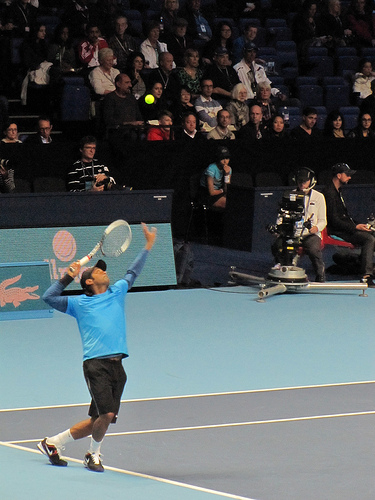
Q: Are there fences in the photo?
A: No, there are no fences.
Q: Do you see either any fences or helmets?
A: No, there are no fences or helmets.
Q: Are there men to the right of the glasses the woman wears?
A: Yes, there is a man to the right of the glasses.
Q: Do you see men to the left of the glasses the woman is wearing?
A: No, the man is to the right of the glasses.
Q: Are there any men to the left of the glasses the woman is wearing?
A: No, the man is to the right of the glasses.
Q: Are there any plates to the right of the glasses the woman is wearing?
A: No, there is a man to the right of the glasses.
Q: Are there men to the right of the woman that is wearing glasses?
A: Yes, there is a man to the right of the woman.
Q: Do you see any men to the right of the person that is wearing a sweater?
A: Yes, there is a man to the right of the woman.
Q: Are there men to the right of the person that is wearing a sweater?
A: Yes, there is a man to the right of the woman.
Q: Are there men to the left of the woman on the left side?
A: No, the man is to the right of the woman.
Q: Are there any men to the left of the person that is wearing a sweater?
A: No, the man is to the right of the woman.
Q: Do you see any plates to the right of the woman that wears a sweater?
A: No, there is a man to the right of the woman.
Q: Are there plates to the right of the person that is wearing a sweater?
A: No, there is a man to the right of the woman.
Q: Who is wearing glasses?
A: The man is wearing glasses.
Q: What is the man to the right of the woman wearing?
A: The man is wearing glasses.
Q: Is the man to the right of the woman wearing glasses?
A: Yes, the man is wearing glasses.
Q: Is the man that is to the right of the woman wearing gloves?
A: No, the man is wearing glasses.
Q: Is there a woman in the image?
A: Yes, there is a woman.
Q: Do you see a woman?
A: Yes, there is a woman.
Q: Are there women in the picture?
A: Yes, there is a woman.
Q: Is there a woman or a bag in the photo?
A: Yes, there is a woman.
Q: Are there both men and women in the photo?
A: Yes, there are both a woman and men.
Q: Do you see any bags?
A: No, there are no bags.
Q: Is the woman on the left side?
A: Yes, the woman is on the left of the image.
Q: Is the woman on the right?
A: No, the woman is on the left of the image.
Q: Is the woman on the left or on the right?
A: The woman is on the left of the image.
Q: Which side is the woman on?
A: The woman is on the left of the image.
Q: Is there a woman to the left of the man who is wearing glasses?
A: Yes, there is a woman to the left of the man.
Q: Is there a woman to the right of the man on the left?
A: No, the woman is to the left of the man.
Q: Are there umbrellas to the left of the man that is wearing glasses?
A: No, there is a woman to the left of the man.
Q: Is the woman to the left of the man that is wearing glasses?
A: Yes, the woman is to the left of the man.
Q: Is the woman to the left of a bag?
A: No, the woman is to the left of the man.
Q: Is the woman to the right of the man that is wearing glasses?
A: No, the woman is to the left of the man.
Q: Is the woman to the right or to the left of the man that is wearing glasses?
A: The woman is to the left of the man.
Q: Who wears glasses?
A: The woman wears glasses.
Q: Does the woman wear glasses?
A: Yes, the woman wears glasses.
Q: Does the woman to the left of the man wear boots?
A: No, the woman wears glasses.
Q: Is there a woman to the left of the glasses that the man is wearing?
A: Yes, there is a woman to the left of the glasses.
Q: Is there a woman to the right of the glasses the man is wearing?
A: No, the woman is to the left of the glasses.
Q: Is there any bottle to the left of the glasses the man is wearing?
A: No, there is a woman to the left of the glasses.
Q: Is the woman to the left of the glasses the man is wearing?
A: Yes, the woman is to the left of the glasses.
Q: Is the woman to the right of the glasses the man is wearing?
A: No, the woman is to the left of the glasses.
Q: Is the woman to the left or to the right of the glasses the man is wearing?
A: The woman is to the left of the glasses.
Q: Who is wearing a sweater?
A: The woman is wearing a sweater.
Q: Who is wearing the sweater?
A: The woman is wearing a sweater.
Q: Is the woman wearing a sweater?
A: Yes, the woman is wearing a sweater.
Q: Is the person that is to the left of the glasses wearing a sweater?
A: Yes, the woman is wearing a sweater.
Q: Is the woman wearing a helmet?
A: No, the woman is wearing a sweater.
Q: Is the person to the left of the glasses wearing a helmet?
A: No, the woman is wearing a sweater.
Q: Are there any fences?
A: No, there are no fences.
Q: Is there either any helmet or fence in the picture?
A: No, there are no fences or helmets.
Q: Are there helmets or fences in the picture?
A: No, there are no fences or helmets.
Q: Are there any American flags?
A: No, there are no American flags.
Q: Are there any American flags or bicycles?
A: No, there are no American flags or bicycles.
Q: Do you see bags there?
A: No, there are no bags.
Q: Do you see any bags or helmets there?
A: No, there are no bags or helmets.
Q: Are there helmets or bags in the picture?
A: No, there are no bags or helmets.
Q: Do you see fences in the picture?
A: No, there are no fences.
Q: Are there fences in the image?
A: No, there are no fences.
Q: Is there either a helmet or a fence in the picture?
A: No, there are no fences or helmets.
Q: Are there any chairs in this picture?
A: Yes, there is a chair.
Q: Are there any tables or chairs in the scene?
A: Yes, there is a chair.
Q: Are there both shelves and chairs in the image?
A: No, there is a chair but no shelves.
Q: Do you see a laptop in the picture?
A: No, there are no laptops.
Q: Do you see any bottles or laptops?
A: No, there are no laptops or bottles.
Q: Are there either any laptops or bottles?
A: No, there are no laptops or bottles.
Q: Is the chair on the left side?
A: No, the chair is on the right of the image.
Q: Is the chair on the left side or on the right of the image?
A: The chair is on the right of the image.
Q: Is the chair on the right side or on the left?
A: The chair is on the right of the image.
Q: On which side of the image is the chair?
A: The chair is on the right of the image.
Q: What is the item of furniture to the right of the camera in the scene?
A: The piece of furniture is a chair.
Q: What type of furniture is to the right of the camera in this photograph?
A: The piece of furniture is a chair.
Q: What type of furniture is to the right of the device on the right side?
A: The piece of furniture is a chair.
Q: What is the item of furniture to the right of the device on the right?
A: The piece of furniture is a chair.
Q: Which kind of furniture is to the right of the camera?
A: The piece of furniture is a chair.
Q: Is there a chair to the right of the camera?
A: Yes, there is a chair to the right of the camera.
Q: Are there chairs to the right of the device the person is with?
A: Yes, there is a chair to the right of the camera.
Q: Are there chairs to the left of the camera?
A: No, the chair is to the right of the camera.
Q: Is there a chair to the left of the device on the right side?
A: No, the chair is to the right of the camera.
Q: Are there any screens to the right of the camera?
A: No, there is a chair to the right of the camera.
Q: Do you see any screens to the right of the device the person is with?
A: No, there is a chair to the right of the camera.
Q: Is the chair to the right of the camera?
A: Yes, the chair is to the right of the camera.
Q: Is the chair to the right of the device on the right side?
A: Yes, the chair is to the right of the camera.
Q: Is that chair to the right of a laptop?
A: No, the chair is to the right of the camera.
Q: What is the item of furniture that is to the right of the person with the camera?
A: The piece of furniture is a chair.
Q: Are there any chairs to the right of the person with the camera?
A: Yes, there is a chair to the right of the person.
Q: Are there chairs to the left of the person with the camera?
A: No, the chair is to the right of the person.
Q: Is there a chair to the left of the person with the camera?
A: No, the chair is to the right of the person.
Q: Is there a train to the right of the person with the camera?
A: No, there is a chair to the right of the person.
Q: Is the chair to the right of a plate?
A: No, the chair is to the right of the person.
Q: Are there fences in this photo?
A: No, there are no fences.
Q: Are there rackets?
A: Yes, there is a racket.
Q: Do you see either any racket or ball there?
A: Yes, there is a racket.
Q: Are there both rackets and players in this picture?
A: Yes, there are both a racket and a player.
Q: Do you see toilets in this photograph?
A: No, there are no toilets.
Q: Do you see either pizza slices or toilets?
A: No, there are no toilets or pizza slices.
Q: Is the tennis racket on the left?
A: Yes, the tennis racket is on the left of the image.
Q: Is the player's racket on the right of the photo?
A: No, the tennis racket is on the left of the image.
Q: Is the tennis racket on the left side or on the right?
A: The tennis racket is on the left of the image.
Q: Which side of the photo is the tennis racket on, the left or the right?
A: The tennis racket is on the left of the image.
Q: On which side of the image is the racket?
A: The racket is on the left of the image.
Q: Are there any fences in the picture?
A: No, there are no fences.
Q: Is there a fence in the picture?
A: No, there are no fences.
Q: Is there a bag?
A: No, there are no bags.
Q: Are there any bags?
A: No, there are no bags.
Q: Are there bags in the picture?
A: No, there are no bags.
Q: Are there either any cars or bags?
A: No, there are no bags or cars.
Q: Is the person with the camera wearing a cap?
A: Yes, the person is wearing a cap.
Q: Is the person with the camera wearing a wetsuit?
A: No, the person is wearing a cap.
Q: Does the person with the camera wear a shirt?
A: Yes, the person wears a shirt.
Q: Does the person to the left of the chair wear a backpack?
A: No, the person wears a shirt.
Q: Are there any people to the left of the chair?
A: Yes, there is a person to the left of the chair.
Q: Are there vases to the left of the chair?
A: No, there is a person to the left of the chair.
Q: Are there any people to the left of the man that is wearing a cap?
A: Yes, there is a person to the left of the man.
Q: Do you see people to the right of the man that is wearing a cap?
A: No, the person is to the left of the man.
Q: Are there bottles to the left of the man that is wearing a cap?
A: No, there is a person to the left of the man.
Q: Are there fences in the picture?
A: No, there are no fences.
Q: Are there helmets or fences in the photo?
A: No, there are no fences or helmets.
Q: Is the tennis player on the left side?
A: Yes, the player is on the left of the image.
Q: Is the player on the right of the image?
A: No, the player is on the left of the image.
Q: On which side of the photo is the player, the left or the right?
A: The player is on the left of the image.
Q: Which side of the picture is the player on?
A: The player is on the left of the image.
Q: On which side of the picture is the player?
A: The player is on the left of the image.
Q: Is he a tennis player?
A: Yes, this is a tennis player.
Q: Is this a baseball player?
A: No, this is a tennis player.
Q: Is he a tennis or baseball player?
A: This is a tennis player.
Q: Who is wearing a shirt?
A: The player is wearing a shirt.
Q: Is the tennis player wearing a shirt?
A: Yes, the player is wearing a shirt.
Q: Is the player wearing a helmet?
A: No, the player is wearing a shirt.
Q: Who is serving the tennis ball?
A: The player is serving the tennis ball.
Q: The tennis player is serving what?
A: The player is serving a tennis ball.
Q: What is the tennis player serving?
A: The player is serving a tennis ball.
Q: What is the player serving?
A: The player is serving a tennis ball.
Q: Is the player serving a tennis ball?
A: Yes, the player is serving a tennis ball.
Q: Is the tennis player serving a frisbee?
A: No, the player is serving a tennis ball.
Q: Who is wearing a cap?
A: The player is wearing a cap.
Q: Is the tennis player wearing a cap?
A: Yes, the player is wearing a cap.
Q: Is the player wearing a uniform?
A: No, the player is wearing a cap.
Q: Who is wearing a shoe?
A: The player is wearing a shoe.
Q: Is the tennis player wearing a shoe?
A: Yes, the player is wearing a shoe.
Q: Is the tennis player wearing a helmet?
A: No, the player is wearing a shoe.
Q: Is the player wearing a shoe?
A: Yes, the player is wearing a shoe.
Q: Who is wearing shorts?
A: The player is wearing shorts.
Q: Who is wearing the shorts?
A: The player is wearing shorts.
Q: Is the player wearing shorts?
A: Yes, the player is wearing shorts.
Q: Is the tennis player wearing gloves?
A: No, the player is wearing shorts.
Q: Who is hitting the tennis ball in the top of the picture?
A: The player is hitting the tennis ball.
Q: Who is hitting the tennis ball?
A: The player is hitting the tennis ball.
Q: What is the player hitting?
A: The player is hitting the tennis ball.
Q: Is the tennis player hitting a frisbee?
A: No, the player is hitting the tennis ball.